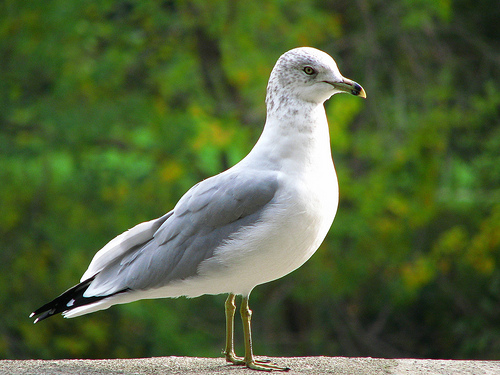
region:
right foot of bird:
[254, 338, 281, 373]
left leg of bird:
[221, 294, 239, 357]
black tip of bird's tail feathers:
[34, 284, 90, 325]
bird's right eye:
[298, 53, 320, 88]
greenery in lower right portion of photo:
[403, 249, 498, 342]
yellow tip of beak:
[355, 83, 375, 108]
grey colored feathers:
[176, 200, 234, 248]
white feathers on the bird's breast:
[291, 177, 326, 252]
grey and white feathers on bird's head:
[266, 52, 292, 114]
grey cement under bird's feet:
[352, 354, 439, 374]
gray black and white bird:
[102, 43, 369, 286]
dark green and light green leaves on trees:
[11, 9, 63, 49]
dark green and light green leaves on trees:
[40, 143, 78, 190]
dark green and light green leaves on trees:
[9, 259, 45, 280]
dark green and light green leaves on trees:
[114, 150, 162, 188]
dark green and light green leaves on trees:
[354, 179, 381, 223]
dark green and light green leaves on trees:
[334, 263, 386, 307]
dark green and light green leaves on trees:
[367, 162, 409, 215]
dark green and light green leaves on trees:
[160, 70, 215, 125]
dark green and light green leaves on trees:
[395, 41, 434, 111]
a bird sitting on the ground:
[22, 37, 412, 373]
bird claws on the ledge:
[210, 284, 302, 372]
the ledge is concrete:
[4, 336, 495, 371]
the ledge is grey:
[0, 349, 497, 370]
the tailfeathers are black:
[13, 244, 164, 336]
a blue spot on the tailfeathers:
[61, 295, 83, 312]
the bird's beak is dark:
[325, 77, 372, 101]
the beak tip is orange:
[357, 89, 371, 105]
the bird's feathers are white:
[42, 37, 369, 341]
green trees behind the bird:
[2, 2, 496, 344]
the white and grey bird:
[13, 35, 372, 371]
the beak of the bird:
[326, 63, 371, 112]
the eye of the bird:
[299, 59, 321, 83]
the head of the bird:
[257, 30, 371, 123]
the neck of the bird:
[250, 99, 343, 172]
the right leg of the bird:
[239, 293, 295, 373]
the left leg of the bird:
[216, 287, 241, 360]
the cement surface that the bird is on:
[5, 355, 497, 373]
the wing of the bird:
[27, 171, 319, 327]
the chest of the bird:
[254, 149, 347, 314]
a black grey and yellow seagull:
[29, 41, 373, 369]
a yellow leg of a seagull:
[223, 290, 238, 360]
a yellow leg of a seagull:
[240, 290, 256, 360]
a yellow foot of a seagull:
[230, 351, 269, 363]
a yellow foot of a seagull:
[247, 355, 285, 371]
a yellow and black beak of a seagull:
[332, 74, 364, 96]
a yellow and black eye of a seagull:
[299, 63, 314, 75]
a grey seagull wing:
[105, 171, 282, 277]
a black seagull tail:
[27, 277, 109, 325]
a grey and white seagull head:
[271, 43, 334, 126]